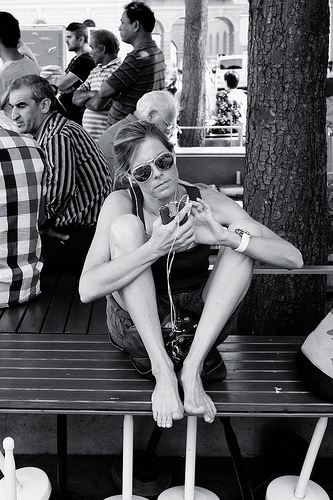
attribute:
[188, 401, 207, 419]
toe — curled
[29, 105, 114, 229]
shirt — black , white 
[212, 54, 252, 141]
stand — long, white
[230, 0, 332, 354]
tree — wide, trunk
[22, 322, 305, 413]
surface — wooden, seating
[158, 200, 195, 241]
phone — cell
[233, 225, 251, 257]
watch — white, shiny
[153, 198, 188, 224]
phone — mobile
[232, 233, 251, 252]
band — white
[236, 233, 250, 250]
band — white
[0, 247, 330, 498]
bench — wooden, slatted